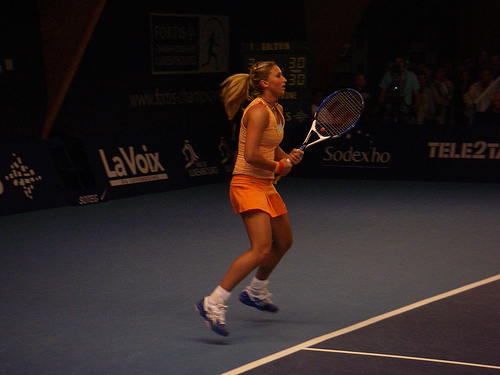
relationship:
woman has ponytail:
[191, 57, 297, 339] [215, 61, 285, 110]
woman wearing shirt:
[191, 57, 305, 339] [233, 95, 286, 179]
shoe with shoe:
[190, 291, 228, 335] [193, 295, 234, 338]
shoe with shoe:
[229, 287, 279, 315] [234, 287, 279, 315]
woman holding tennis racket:
[191, 57, 305, 339] [275, 88, 366, 178]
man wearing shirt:
[374, 52, 425, 137] [378, 70, 425, 113]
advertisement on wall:
[87, 127, 176, 204] [0, 107, 498, 219]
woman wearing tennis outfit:
[191, 57, 305, 339] [227, 97, 287, 217]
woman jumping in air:
[191, 57, 305, 339] [169, 298, 218, 338]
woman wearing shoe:
[191, 57, 297, 339] [192, 294, 237, 342]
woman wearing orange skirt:
[191, 57, 297, 339] [227, 173, 286, 216]